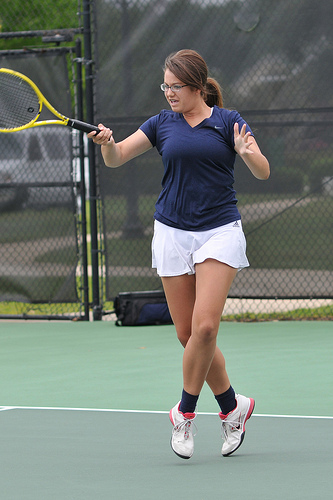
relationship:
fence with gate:
[0, 0, 333, 322] [0, 28, 96, 322]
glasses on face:
[159, 80, 188, 94] [159, 65, 197, 114]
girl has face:
[87, 45, 272, 461] [159, 65, 197, 114]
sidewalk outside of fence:
[88, 295, 330, 320] [0, 1, 331, 319]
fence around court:
[207, 18, 327, 159] [51, 25, 307, 427]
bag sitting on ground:
[91, 277, 207, 337] [0, 317, 331, 498]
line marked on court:
[0, 407, 12, 410] [0, 318, 331, 499]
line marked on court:
[0, 405, 331, 418] [0, 318, 331, 499]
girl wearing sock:
[87, 45, 272, 461] [212, 384, 236, 417]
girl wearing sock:
[87, 45, 272, 461] [176, 388, 199, 414]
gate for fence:
[0, 33, 89, 320] [1, 1, 330, 498]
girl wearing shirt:
[87, 45, 272, 461] [157, 106, 251, 217]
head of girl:
[157, 48, 208, 114] [87, 49, 269, 459]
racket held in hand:
[0, 68, 110, 141] [84, 121, 113, 145]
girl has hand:
[87, 49, 269, 459] [84, 121, 113, 145]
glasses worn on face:
[160, 82, 189, 93] [162, 69, 185, 112]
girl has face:
[87, 45, 272, 461] [162, 69, 185, 112]